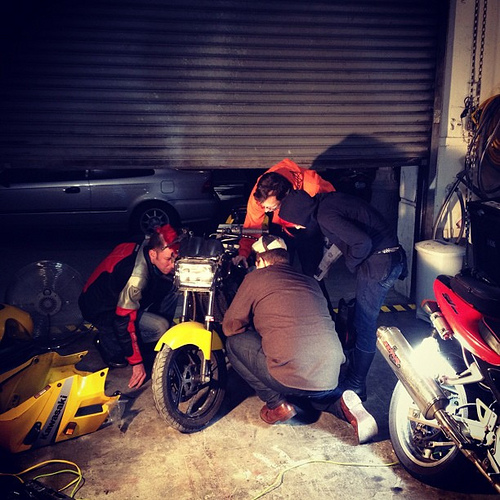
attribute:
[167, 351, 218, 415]
spoke — in the picture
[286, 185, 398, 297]
jacket — black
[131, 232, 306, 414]
motorcycle — yellow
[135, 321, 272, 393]
wheel guard — in the picture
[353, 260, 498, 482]
motorcycle — red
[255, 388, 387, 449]
shoes — in the picture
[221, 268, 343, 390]
shirt — grey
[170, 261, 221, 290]
headlight — in the picture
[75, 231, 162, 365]
jacket — red, black, silver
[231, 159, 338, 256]
jacket — orange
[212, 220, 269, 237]
handlebar — black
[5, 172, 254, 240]
car — in the picture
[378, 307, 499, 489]
wheel — black 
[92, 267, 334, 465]
motorcycle — yellow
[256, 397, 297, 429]
shoe — brown 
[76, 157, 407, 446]
men motorcycle — in the picture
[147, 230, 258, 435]
motorcycle — yellow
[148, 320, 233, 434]
wheel — black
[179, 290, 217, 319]
cycle shocks — black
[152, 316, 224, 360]
fender — yellow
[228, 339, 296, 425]
pants — in the picture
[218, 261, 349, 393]
brown shirt — brown 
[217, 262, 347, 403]
shirt — long sleeve, brown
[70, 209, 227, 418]
man — in the picture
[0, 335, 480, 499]
floor — in the picture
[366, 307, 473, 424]
muffler — silver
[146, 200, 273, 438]
motorcycle — yellow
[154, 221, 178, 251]
mohawk — red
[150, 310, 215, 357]
frame — yellow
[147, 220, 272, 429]
motorcycle — yellow